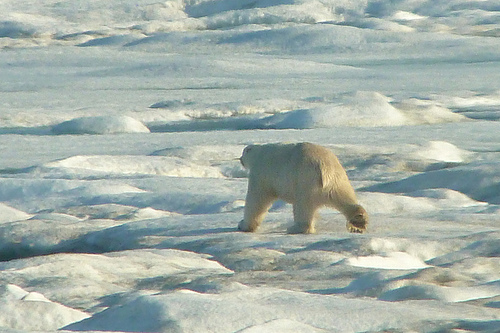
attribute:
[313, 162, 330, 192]
tail — short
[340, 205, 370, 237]
foot — large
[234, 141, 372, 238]
bear — polar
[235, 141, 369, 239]
polar bear — large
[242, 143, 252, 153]
ear — small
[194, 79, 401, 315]
bear — white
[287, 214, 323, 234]
foot — large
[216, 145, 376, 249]
bear — polar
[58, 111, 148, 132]
hill — small